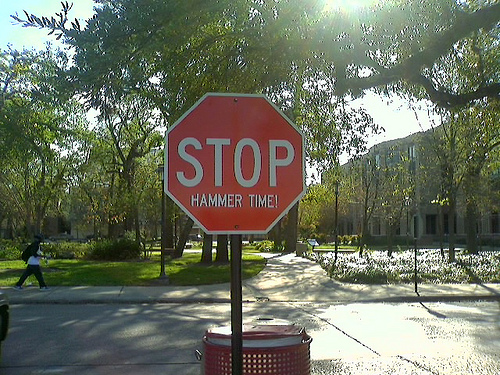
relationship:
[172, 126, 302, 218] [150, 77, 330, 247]
saying on sign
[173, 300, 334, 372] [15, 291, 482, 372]
can on street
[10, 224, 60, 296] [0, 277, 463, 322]
man walking on curb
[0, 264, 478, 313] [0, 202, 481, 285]
sidewalk near park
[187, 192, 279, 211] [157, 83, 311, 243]
words on sign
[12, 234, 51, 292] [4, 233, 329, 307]
man walks on sidewalk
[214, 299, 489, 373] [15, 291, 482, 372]
sunlight shines on street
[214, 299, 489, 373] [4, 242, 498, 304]
sunlight shines on sidewalk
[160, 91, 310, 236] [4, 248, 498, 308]
sign on sidewalk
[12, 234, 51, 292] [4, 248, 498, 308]
man walking down sidewalk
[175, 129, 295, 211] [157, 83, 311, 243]
writing on sign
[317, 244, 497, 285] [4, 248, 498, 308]
flowers next to sidewalk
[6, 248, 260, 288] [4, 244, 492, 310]
grass next to sidewalk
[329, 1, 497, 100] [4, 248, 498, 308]
branch next to sidewalk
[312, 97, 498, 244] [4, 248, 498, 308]
building next to sidewalk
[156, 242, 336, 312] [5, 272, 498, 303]
path leading from sidewalk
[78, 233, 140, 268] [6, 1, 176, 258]
shrubbery growing under trees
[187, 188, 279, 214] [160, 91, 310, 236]
saying on sign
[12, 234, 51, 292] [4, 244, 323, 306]
man walking on sidewalk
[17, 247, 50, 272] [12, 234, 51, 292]
shirt on man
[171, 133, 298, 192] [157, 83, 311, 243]
writing on sign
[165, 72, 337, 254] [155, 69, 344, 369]
words on sign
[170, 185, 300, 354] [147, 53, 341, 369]
post on sign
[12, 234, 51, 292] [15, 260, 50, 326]
man wearing pants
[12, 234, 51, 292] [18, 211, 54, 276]
man wearing shirt